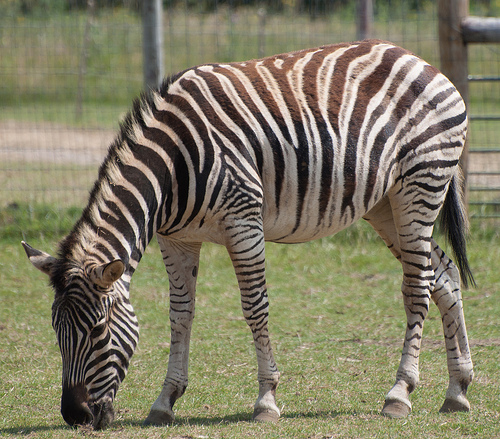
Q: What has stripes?
A: Zebra.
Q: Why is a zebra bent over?
A: It is eating grass.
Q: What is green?
A: Grass.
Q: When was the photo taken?
A: Daytime.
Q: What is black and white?
A: The zebra.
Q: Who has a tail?
A: A zebra.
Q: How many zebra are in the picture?
A: One.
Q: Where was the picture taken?
A: In a zoo.